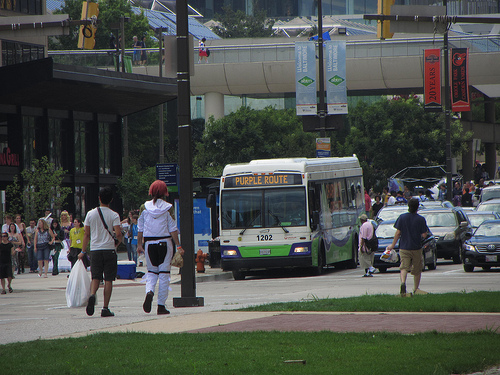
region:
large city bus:
[215, 146, 395, 290]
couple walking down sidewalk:
[81, 178, 191, 335]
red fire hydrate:
[191, 243, 215, 277]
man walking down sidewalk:
[388, 193, 435, 295]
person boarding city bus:
[210, 140, 378, 285]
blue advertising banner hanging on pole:
[285, 20, 361, 130]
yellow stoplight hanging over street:
[66, 5, 111, 60]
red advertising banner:
[411, 40, 491, 132]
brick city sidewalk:
[100, 280, 496, 340]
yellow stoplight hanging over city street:
[358, 4, 409, 54]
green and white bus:
[190, 117, 403, 315]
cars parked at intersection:
[349, 184, 499, 280]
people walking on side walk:
[60, 164, 214, 332]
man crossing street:
[342, 188, 383, 300]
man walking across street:
[358, 187, 450, 330]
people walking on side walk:
[0, 198, 89, 314]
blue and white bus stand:
[148, 169, 244, 291]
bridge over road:
[52, 15, 499, 87]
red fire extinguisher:
[184, 236, 224, 292]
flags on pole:
[275, 23, 386, 160]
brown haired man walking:
[388, 196, 432, 293]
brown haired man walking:
[65, 184, 122, 316]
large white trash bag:
[66, 254, 93, 306]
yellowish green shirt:
[67, 226, 86, 258]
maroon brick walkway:
[195, 311, 499, 338]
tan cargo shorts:
[395, 248, 426, 270]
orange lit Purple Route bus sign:
[228, 174, 293, 186]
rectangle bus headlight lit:
[221, 247, 238, 256]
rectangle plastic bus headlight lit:
[291, 245, 308, 251]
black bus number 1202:
[255, 233, 273, 242]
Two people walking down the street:
[51, 179, 193, 339]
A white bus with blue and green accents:
[207, 148, 390, 296]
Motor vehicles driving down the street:
[196, 154, 498, 308]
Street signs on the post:
[281, 11, 356, 143]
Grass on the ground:
[4, 327, 494, 374]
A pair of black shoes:
[134, 291, 180, 322]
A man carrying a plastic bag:
[51, 184, 131, 336]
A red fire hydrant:
[194, 246, 211, 280]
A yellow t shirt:
[63, 221, 99, 261]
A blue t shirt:
[387, 208, 435, 260]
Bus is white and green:
[208, 139, 376, 283]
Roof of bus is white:
[215, 142, 370, 189]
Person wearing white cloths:
[125, 171, 189, 326]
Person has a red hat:
[122, 170, 194, 325]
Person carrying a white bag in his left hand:
[50, 179, 134, 326]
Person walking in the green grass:
[373, 188, 441, 305]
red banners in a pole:
[413, 37, 475, 120]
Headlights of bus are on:
[213, 241, 313, 262]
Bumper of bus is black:
[216, 255, 318, 277]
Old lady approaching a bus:
[353, 204, 380, 278]